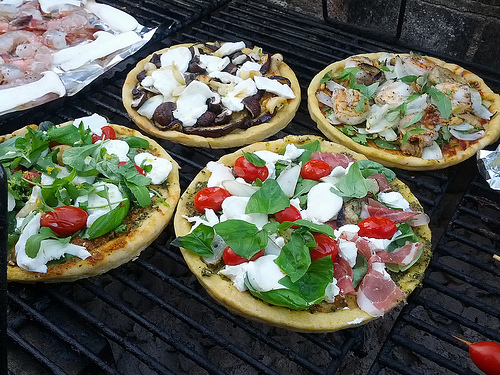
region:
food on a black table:
[8, 5, 496, 368]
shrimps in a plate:
[4, 0, 159, 115]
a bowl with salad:
[176, 132, 436, 344]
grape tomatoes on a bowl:
[190, 142, 400, 292]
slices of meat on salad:
[324, 142, 427, 322]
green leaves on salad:
[174, 129, 431, 325]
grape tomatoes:
[189, 180, 237, 211]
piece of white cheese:
[294, 171, 354, 226]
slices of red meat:
[350, 231, 406, 316]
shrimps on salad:
[326, 60, 480, 151]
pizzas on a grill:
[5, 25, 499, 345]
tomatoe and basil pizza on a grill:
[160, 128, 442, 345]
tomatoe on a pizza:
[187, 180, 231, 219]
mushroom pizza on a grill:
[109, 32, 308, 151]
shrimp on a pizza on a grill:
[327, 78, 379, 129]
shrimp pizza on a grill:
[302, 36, 498, 166]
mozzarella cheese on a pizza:
[167, 73, 222, 127]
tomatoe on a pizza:
[31, 195, 98, 239]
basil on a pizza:
[80, 150, 163, 207]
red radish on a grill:
[437, 322, 498, 374]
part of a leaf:
[268, 267, 300, 317]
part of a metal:
[198, 358, 211, 370]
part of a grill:
[170, 338, 195, 361]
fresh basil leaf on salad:
[214, 218, 267, 260]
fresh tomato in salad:
[190, 184, 234, 216]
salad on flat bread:
[166, 130, 438, 331]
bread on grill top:
[172, 135, 443, 337]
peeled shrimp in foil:
[1, 0, 143, 102]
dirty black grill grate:
[1, 0, 496, 374]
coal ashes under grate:
[11, 124, 498, 374]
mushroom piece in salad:
[152, 98, 182, 130]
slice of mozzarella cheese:
[304, 178, 344, 226]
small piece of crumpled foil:
[474, 140, 499, 193]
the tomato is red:
[196, 176, 238, 241]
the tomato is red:
[253, 189, 319, 242]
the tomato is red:
[308, 157, 336, 189]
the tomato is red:
[195, 175, 226, 214]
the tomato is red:
[308, 243, 346, 273]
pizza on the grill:
[118, 53, 290, 150]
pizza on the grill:
[196, 107, 421, 368]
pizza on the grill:
[310, 52, 496, 189]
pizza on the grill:
[8, 106, 201, 301]